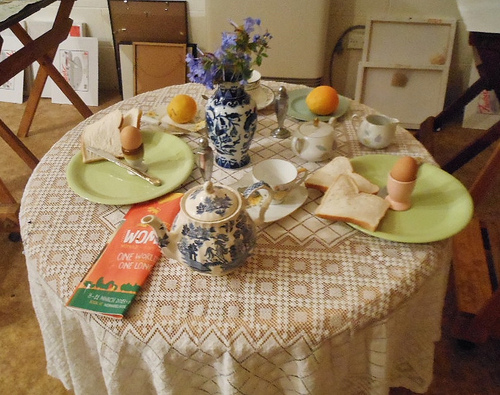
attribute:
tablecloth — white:
[231, 232, 446, 337]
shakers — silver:
[192, 78, 297, 185]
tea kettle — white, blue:
[176, 185, 258, 274]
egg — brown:
[389, 151, 419, 184]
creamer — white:
[327, 103, 411, 156]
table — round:
[12, 67, 477, 379]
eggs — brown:
[389, 150, 416, 181]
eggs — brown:
[119, 122, 141, 149]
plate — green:
[61, 123, 198, 208]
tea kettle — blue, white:
[142, 181, 273, 273]